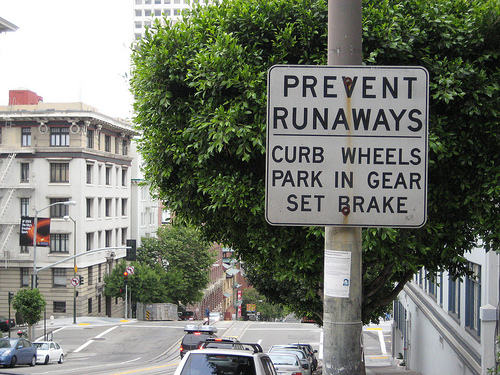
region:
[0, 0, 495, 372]
The view of a street.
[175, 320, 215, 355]
A truck driving down the street.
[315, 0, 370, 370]
A pole is near the street.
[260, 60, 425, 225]
A sign is on the pole.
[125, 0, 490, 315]
A green tree is next to the pole.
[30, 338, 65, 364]
A white car parked on the street.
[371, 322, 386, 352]
A white line painted on a cross walk.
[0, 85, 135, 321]
A building on the other side of the street.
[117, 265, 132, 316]
A traffic signal near the building.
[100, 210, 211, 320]
The trees have green leaves.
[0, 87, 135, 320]
A grey building on one side of the street.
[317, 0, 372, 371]
A pole on the other side of the street.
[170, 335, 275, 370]
A truck is parked on the side of the street.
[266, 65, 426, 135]
The sign says prevent runaways.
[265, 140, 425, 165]
The sign says curb wheels.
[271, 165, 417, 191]
The sign says park in gear.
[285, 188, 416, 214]
The sign says set brake.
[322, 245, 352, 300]
A paper is attached to the sign pole.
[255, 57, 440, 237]
the sign is in black & white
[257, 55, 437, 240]
the sign is warning of parking on a hill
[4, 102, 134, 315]
this is a multi story building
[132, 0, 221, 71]
a super high rise is in the background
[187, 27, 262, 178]
the tree is very thick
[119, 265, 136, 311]
the stop light is red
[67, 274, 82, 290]
the sign says no left turn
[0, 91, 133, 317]
this building looks old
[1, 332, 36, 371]
this vehicle is blue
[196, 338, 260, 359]
this car has a luggage rack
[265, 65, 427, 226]
white and black sign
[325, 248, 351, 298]
white paper on sign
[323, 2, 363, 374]
grey metal electrical post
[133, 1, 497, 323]
tree with green leaves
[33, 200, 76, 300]
grey metal street lamp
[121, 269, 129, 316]
electronic stop light on post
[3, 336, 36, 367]
blue car on street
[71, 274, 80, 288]
no turn sign on post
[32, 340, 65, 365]
white car on street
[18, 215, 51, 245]
black and red sign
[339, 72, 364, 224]
Sign has rust stain down the middle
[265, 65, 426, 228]
Sign is to prevent runaway cars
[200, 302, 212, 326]
Person is walking across the street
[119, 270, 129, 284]
Traffic light is red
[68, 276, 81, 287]
No left turn sign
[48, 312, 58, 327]
White fire hydrant on corner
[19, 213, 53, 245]
City advertising hanging from light pole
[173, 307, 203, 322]
Burgundy car heading up the hill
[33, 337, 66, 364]
Small white car behind blue prius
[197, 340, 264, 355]
Car has a bike rack on top